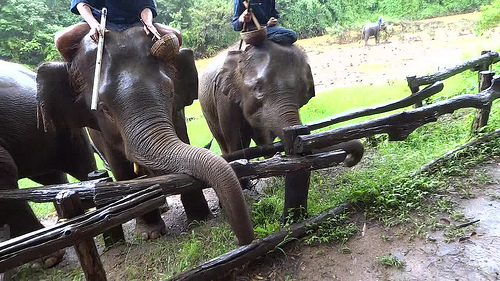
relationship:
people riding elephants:
[46, 0, 306, 59] [1, 32, 325, 229]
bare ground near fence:
[230, 137, 498, 279] [1, 47, 498, 279]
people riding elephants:
[50, 0, 301, 51] [1, 24, 326, 279]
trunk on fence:
[112, 107, 257, 242] [224, 125, 351, 220]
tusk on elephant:
[128, 160, 145, 176] [30, 13, 260, 254]